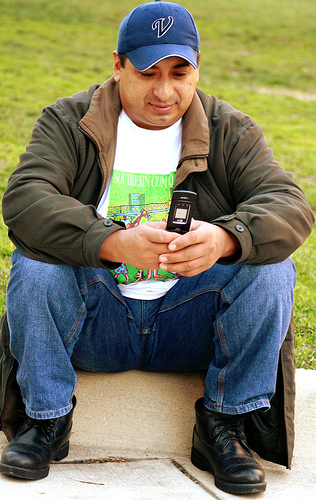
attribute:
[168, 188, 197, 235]
black cellphone — small black cell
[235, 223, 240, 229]
button — tiny, round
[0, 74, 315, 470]
coat — brown, long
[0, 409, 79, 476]
shoe — shiny black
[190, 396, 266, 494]
black shoe — shiny black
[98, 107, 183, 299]
t shirt — white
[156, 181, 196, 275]
phone — black, flip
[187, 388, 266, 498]
boot — black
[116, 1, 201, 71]
hat — blue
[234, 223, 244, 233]
button — brown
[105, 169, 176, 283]
picture — green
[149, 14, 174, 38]
logo — letter V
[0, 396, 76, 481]
shoe — black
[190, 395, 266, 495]
shoe — black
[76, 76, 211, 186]
collar — brown